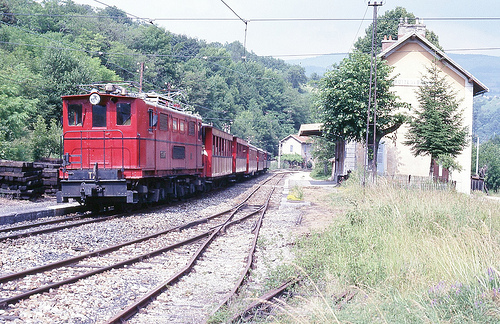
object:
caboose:
[48, 79, 212, 213]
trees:
[314, 45, 410, 187]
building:
[276, 135, 310, 167]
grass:
[285, 175, 500, 321]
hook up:
[79, 182, 106, 202]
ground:
[415, 120, 459, 162]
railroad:
[10, 148, 293, 321]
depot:
[294, 112, 370, 186]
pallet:
[0, 152, 43, 199]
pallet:
[34, 154, 63, 191]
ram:
[57, 169, 129, 204]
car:
[52, 80, 207, 212]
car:
[203, 122, 234, 189]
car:
[231, 132, 248, 178]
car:
[248, 145, 258, 179]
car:
[268, 146, 273, 175]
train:
[53, 82, 273, 212]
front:
[56, 93, 173, 196]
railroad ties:
[0, 156, 55, 197]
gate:
[66, 131, 143, 178]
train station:
[286, 122, 333, 177]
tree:
[413, 61, 465, 185]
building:
[359, 20, 487, 191]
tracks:
[173, 222, 305, 294]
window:
[91, 95, 108, 125]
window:
[67, 101, 83, 123]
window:
[109, 93, 139, 127]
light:
[82, 85, 105, 104]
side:
[392, 175, 484, 321]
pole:
[359, 9, 394, 196]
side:
[390, 132, 413, 176]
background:
[234, 37, 314, 224]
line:
[57, 95, 208, 209]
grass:
[281, 168, 310, 201]